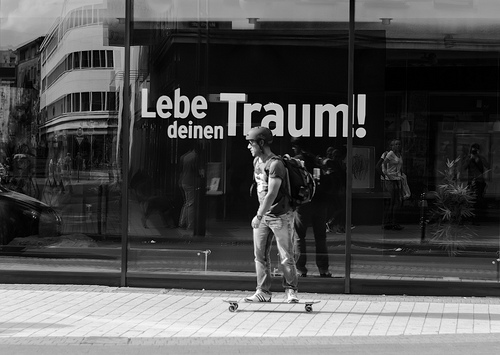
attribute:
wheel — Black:
[303, 303, 313, 315]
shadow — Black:
[254, 301, 498, 326]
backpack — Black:
[282, 154, 319, 211]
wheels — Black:
[225, 302, 314, 317]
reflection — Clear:
[35, 0, 248, 251]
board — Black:
[220, 287, 334, 321]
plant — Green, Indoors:
[421, 157, 479, 258]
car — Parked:
[2, 181, 64, 251]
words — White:
[139, 87, 366, 139]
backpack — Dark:
[278, 151, 317, 207]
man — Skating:
[225, 122, 320, 304]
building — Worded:
[0, 1, 499, 300]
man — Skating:
[243, 124, 304, 300]